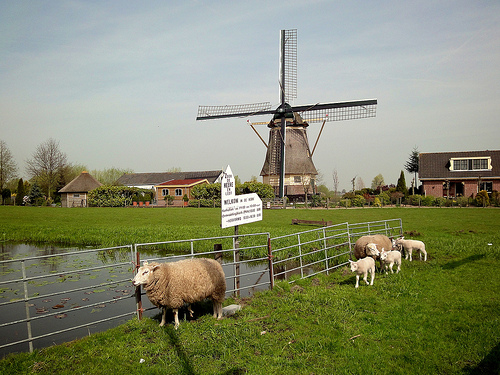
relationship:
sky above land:
[75, 36, 167, 93] [128, 200, 192, 230]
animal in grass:
[348, 257, 375, 288] [279, 305, 419, 362]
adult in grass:
[132, 261, 230, 309] [279, 305, 419, 362]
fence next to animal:
[1, 218, 403, 355] [132, 256, 226, 326]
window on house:
[477, 182, 494, 200] [416, 149, 498, 204]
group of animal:
[348, 232, 425, 285] [348, 257, 375, 288]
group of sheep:
[348, 232, 425, 285] [379, 247, 401, 276]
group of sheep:
[348, 232, 425, 285] [394, 235, 426, 265]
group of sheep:
[348, 232, 425, 285] [353, 231, 398, 263]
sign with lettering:
[221, 164, 263, 229] [221, 196, 261, 218]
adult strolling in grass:
[132, 257, 226, 329] [233, 283, 497, 373]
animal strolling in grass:
[348, 257, 375, 288] [233, 283, 497, 373]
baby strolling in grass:
[380, 248, 402, 275] [233, 283, 497, 373]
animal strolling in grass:
[395, 236, 428, 261] [233, 283, 497, 373]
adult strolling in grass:
[353, 234, 392, 272] [233, 283, 497, 373]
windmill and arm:
[193, 24, 378, 201] [276, 24, 299, 114]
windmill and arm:
[193, 24, 378, 201] [289, 98, 379, 124]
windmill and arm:
[193, 24, 378, 201] [268, 119, 282, 209]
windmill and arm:
[193, 24, 378, 201] [195, 100, 274, 115]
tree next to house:
[31, 138, 71, 206] [63, 169, 106, 216]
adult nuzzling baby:
[353, 234, 392, 272] [380, 248, 402, 275]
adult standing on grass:
[132, 257, 226, 329] [1, 204, 498, 371]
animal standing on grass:
[348, 257, 375, 288] [1, 204, 498, 371]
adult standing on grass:
[353, 234, 392, 272] [1, 204, 498, 371]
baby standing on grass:
[380, 248, 402, 275] [1, 204, 498, 371]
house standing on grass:
[59, 171, 103, 208] [1, 204, 498, 371]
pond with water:
[1, 227, 361, 353] [4, 243, 277, 355]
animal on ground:
[132, 256, 226, 326] [4, 201, 498, 364]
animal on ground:
[347, 253, 377, 289] [4, 201, 498, 364]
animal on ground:
[395, 234, 429, 264] [4, 201, 498, 364]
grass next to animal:
[1, 204, 498, 371] [132, 256, 226, 326]